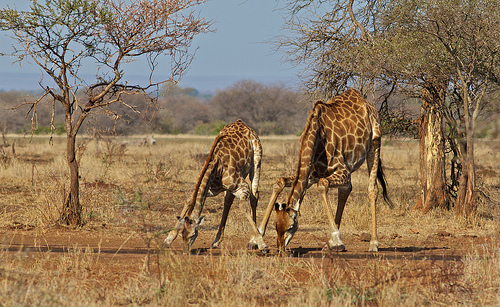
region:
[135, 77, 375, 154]
the tress are blurred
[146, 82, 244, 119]
the tress are blurred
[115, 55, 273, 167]
the tress are blurred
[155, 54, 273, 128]
the tress are blurred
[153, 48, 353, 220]
the tress are blurred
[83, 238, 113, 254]
this is the ground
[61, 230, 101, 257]
the ground is sandy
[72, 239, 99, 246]
the sand is brown in color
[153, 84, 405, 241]
these are two giraffes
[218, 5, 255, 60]
this is the sky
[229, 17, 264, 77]
the sky is blue in color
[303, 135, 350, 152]
the fur is brown in color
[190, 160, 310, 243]
the necks are bent downwards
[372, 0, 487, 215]
this is a tree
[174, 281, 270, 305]
the grass is dry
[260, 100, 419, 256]
The giraffe is kneeling.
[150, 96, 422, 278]
two giraffes eating grass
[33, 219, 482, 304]
The grass is dying.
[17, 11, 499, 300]
They are on a savannah.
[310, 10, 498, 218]
The tree is bare.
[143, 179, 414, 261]
Their knees are bent.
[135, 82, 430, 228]
They are brown and tan.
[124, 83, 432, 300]
The giraffes have brown spots.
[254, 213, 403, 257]
Their hooves are white and tan.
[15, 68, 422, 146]
The trees are in the distance.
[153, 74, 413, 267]
two giraffes drinking water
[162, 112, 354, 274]
a small giraffe near a big giraffe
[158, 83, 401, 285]
two giraffes with front legs extended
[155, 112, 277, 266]
giraffe extend his front legs to drink water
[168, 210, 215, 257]
small head of giraffe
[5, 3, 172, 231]
a tree without flowers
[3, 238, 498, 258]
a tiny creek with water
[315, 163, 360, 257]
right leg is bend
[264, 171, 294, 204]
knee of giraffe is bend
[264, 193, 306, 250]
face of horny giraffe is brown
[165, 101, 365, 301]
the giraffe is eating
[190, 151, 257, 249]
the giraffe is eating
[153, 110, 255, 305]
the giraffe is eating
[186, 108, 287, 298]
the giraffe is eating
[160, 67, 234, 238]
the giraffe is eating